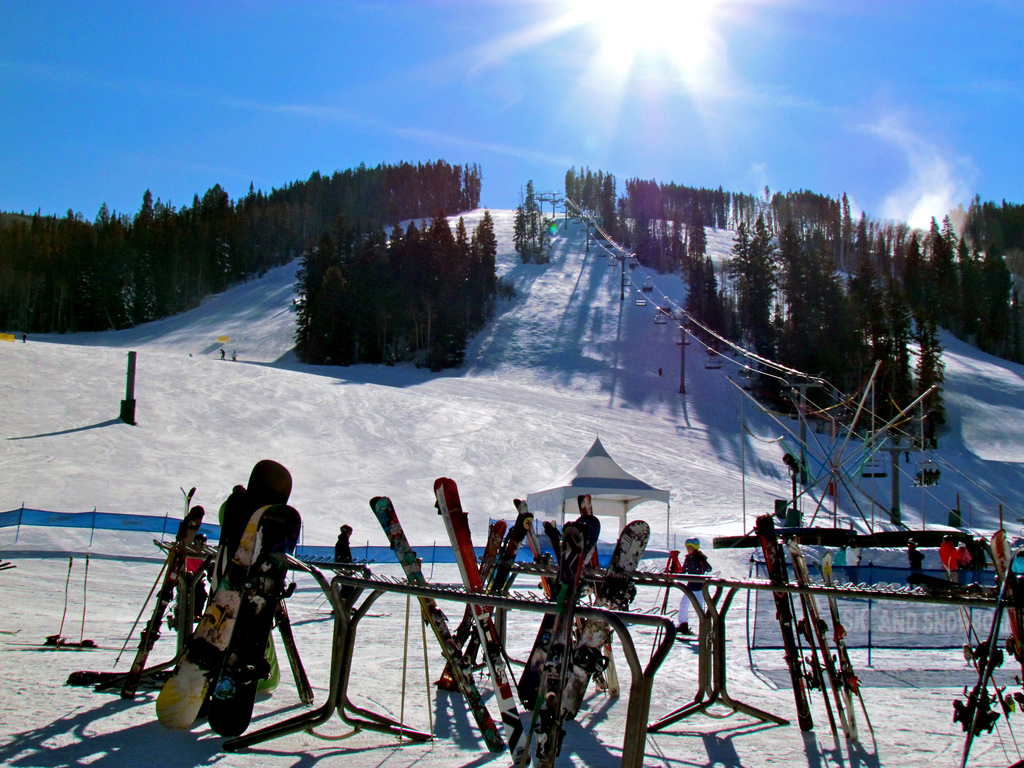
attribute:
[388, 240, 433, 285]
leaves — green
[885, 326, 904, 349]
leaves — green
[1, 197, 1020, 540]
snow — large, body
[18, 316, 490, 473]
snow — body, large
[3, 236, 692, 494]
snow — large, body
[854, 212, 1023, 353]
leaves — green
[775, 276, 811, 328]
leaves — green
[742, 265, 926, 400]
leaves — green